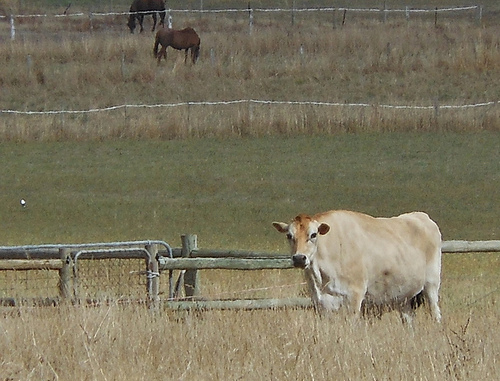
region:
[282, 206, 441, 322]
large white and tan cow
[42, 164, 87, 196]
short green and yellow grass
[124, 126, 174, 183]
short green and yellow grass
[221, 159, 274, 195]
short green and yellow grass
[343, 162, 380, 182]
short green and yellow grass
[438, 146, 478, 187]
short green and yellow grass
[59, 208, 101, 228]
short green and yellow grass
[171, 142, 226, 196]
short green and yellow grass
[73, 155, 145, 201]
short green and yellow grass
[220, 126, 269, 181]
short green and yellow grass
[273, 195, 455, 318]
large cow in field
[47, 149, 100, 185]
short green grass in field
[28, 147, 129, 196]
short green grass in field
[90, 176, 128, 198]
short green grass in field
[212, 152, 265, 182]
short green grass in field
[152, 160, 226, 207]
short green grass in field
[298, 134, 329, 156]
short green grass in field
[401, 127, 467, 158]
short green grass in field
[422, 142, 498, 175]
short green grass in field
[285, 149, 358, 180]
short green grass in field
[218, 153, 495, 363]
a cow in a pasture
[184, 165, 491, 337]
a cow in front of a fence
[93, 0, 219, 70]
two horses in a pasture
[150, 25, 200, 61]
a horse in a pasture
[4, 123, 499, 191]
green grass in a pasture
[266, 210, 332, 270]
the head of a cow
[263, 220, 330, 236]
the ears of a cow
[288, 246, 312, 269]
the nose of a cow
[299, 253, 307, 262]
the nostril of a cow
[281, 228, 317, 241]
the eyes of a cow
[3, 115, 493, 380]
cow in pasture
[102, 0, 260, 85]
two horses in pasture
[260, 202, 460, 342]
cow standing next to fence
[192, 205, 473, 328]
fence behind cow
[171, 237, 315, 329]
fence is made of wood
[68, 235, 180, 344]
metal gate on fence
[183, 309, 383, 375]
tall grass in pasture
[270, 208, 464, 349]
cow standing in tall grass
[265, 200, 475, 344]
cow is light brown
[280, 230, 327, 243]
cows eyes are black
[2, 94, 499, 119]
a long white rope.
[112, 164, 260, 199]
the grass is short and green.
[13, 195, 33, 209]
a little white bird.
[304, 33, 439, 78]
the grass is dark brown and tall.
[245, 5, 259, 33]
a small white poll.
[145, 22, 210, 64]
a small brown horse.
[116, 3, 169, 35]
a dark brown horse.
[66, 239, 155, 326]
a small grey fence.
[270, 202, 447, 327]
a big white and brown cow.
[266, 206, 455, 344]
the cow is standing in the grass.